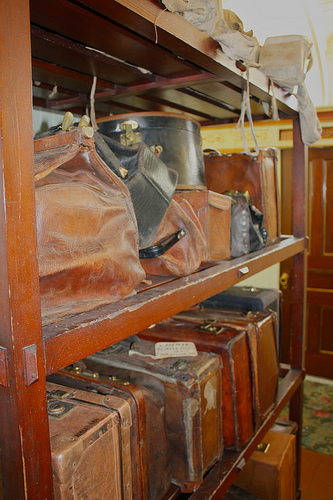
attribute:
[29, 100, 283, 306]
luggage — very old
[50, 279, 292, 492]
luggage — very old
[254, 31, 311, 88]
bag — white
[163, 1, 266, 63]
bag — white